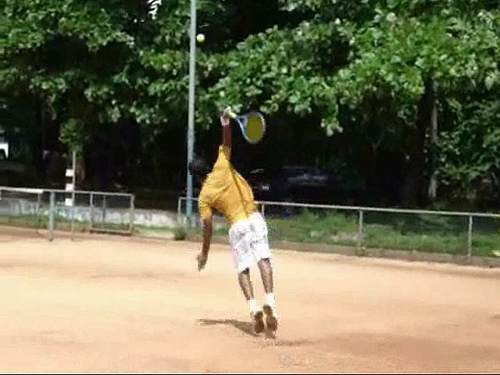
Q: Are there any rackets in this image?
A: Yes, there is a racket.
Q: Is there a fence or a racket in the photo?
A: Yes, there is a racket.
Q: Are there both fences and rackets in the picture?
A: Yes, there are both a racket and a fence.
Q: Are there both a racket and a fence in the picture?
A: Yes, there are both a racket and a fence.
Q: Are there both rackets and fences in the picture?
A: Yes, there are both a racket and a fence.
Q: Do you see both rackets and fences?
A: Yes, there are both a racket and a fence.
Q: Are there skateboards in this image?
A: No, there are no skateboards.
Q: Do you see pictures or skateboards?
A: No, there are no skateboards or pictures.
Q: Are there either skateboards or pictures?
A: No, there are no skateboards or pictures.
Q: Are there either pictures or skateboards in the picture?
A: No, there are no skateboards or pictures.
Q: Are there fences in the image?
A: Yes, there is a fence.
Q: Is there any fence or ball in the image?
A: Yes, there is a fence.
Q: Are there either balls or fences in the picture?
A: Yes, there is a fence.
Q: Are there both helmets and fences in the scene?
A: No, there is a fence but no helmets.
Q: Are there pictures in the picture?
A: No, there are no pictures.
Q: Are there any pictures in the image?
A: No, there are no pictures.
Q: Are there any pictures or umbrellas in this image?
A: No, there are no pictures or umbrellas.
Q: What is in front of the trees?
A: The fence is in front of the trees.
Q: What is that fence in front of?
A: The fence is in front of the trees.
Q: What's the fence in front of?
A: The fence is in front of the trees.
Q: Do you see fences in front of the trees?
A: Yes, there is a fence in front of the trees.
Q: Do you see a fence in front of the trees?
A: Yes, there is a fence in front of the trees.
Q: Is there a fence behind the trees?
A: No, the fence is in front of the trees.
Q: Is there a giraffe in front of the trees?
A: No, there is a fence in front of the trees.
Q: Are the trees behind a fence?
A: Yes, the trees are behind a fence.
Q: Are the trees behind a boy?
A: No, the trees are behind a fence.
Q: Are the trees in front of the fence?
A: No, the trees are behind the fence.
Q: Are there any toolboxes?
A: No, there are no toolboxes.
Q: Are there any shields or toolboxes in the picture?
A: No, there are no toolboxes or shields.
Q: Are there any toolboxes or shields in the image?
A: No, there are no toolboxes or shields.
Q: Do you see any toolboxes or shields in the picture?
A: No, there are no toolboxes or shields.